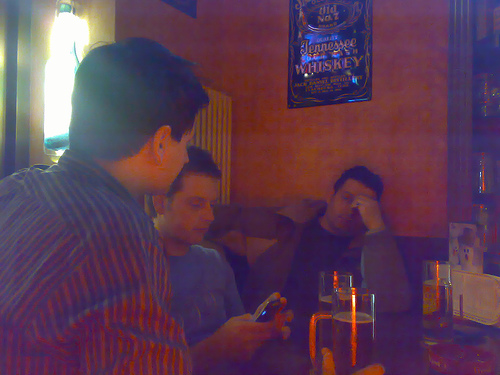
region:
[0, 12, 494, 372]
three men at a pub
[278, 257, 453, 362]
three glasses of beer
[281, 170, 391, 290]
a man touching his face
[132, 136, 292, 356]
a man looking at his cellphone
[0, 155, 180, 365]
a striped dress shirt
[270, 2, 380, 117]
a sign for Tennessee Whiskey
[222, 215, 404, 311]
a gray brown coat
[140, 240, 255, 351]
a light blue tshirt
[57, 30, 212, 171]
short brown hair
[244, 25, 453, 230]
brown orange wallpaper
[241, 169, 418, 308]
a man with his hand on his face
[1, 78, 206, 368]
a man i a striped shirt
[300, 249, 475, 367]
thre glasses on the table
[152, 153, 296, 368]
a man on a cell phone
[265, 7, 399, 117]
a jack daniels whiskey sign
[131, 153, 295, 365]
a man in a blue shirt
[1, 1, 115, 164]
a light on the wall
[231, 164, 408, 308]
man in a grey jacket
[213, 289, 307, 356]
black cell phone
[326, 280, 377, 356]
Light reflecting off a glass beer mug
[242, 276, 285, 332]
A man using a phone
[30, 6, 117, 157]
Light coming through a window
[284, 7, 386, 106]
A metal whiskey sign on a wall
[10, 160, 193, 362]
A striped shirt on a man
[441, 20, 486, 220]
A wooden door frame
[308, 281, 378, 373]
A hand grasping a beer mug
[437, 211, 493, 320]
A snowman picture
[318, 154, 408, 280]
A man resting his head on his hand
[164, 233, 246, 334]
A blue shirt on a man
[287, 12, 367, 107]
poster on the wall.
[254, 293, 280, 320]
cell phone in man's hands.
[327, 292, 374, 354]
mug on the table.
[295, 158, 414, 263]
man leaning against the wall.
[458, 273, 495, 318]
menus on the table.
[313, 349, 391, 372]
man's hand on the mug.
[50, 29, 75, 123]
light coming in the window.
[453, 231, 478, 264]
picture of a snowman.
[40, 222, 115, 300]
stripes on man's shirt.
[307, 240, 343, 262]
black shirt on man's torso.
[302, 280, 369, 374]
full glass beer mug with handle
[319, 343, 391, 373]
hand holding beer mug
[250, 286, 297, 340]
hand holding small cell phone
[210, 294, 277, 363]
hand holding small cell phone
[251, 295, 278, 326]
small plastic cell phone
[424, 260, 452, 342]
clear glass full of liquid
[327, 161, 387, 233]
hand on man's face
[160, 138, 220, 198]
brown hair of man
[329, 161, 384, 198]
brown hair of man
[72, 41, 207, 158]
brown hair of man